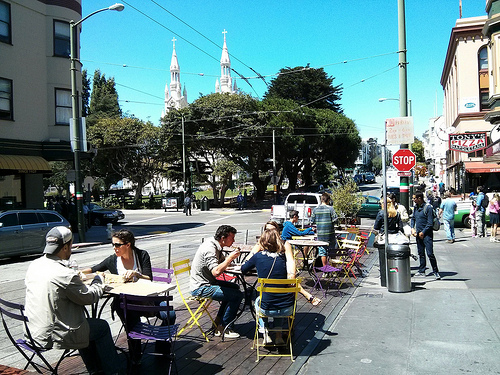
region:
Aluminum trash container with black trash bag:
[387, 243, 411, 293]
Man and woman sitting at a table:
[22, 226, 172, 371]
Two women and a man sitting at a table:
[187, 220, 320, 361]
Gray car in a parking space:
[0, 208, 73, 264]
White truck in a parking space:
[269, 191, 331, 227]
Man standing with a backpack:
[410, 190, 442, 281]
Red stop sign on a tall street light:
[391, 0, 416, 230]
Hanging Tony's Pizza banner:
[447, 130, 489, 156]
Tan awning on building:
[0, 152, 51, 172]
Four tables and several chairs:
[0, 223, 375, 374]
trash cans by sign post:
[374, 225, 415, 298]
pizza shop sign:
[439, 124, 499, 156]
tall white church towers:
[152, 15, 249, 139]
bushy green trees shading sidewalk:
[102, 76, 355, 176]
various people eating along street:
[41, 190, 377, 355]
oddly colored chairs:
[9, 214, 378, 374]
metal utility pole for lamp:
[22, 0, 156, 227]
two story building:
[424, 16, 498, 188]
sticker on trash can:
[386, 266, 401, 278]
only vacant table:
[285, 236, 352, 286]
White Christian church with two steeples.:
[121, 28, 251, 194]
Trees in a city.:
[78, 64, 361, 208]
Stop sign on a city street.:
[391, 148, 416, 171]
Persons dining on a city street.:
[23, 191, 337, 373]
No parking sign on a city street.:
[385, 116, 415, 143]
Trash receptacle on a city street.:
[386, 243, 411, 293]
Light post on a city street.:
[67, 2, 124, 243]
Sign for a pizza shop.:
[448, 131, 487, 153]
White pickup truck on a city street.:
[270, 192, 337, 227]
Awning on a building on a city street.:
[1, 154, 53, 174]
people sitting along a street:
[37, 188, 343, 366]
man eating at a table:
[200, 221, 247, 304]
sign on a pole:
[381, 145, 394, 246]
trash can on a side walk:
[371, 228, 407, 296]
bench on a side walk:
[152, 193, 173, 213]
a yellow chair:
[240, 270, 325, 360]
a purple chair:
[140, 262, 180, 362]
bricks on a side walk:
[186, 330, 256, 370]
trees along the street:
[201, 85, 369, 152]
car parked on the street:
[3, 207, 75, 259]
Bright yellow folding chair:
[248, 276, 299, 363]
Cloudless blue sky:
[79, 2, 489, 136]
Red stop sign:
[392, 148, 417, 171]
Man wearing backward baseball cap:
[23, 225, 123, 373]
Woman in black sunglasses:
[79, 229, 179, 366]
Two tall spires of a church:
[160, 28, 237, 119]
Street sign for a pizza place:
[447, 131, 489, 153]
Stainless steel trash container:
[382, 242, 410, 294]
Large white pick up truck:
[267, 190, 336, 225]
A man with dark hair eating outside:
[186, 221, 245, 340]